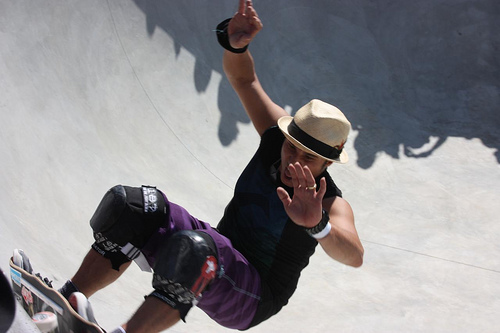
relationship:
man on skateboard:
[10, 2, 363, 331] [8, 256, 108, 332]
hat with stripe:
[278, 98, 350, 164] [289, 118, 343, 158]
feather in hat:
[333, 141, 347, 163] [278, 98, 350, 164]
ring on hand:
[306, 184, 317, 190] [276, 162, 327, 229]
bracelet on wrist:
[313, 222, 333, 239] [312, 213, 337, 246]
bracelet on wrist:
[301, 211, 329, 233] [312, 213, 337, 246]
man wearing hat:
[10, 2, 363, 331] [278, 98, 350, 164]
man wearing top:
[10, 2, 363, 331] [216, 126, 341, 305]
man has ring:
[10, 2, 363, 331] [306, 184, 317, 190]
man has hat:
[10, 2, 363, 331] [278, 98, 350, 164]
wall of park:
[0, 1, 498, 332] [0, 2, 498, 333]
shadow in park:
[134, 0, 499, 168] [0, 2, 498, 333]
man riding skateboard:
[10, 2, 363, 331] [8, 256, 108, 332]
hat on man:
[278, 98, 350, 164] [10, 2, 363, 331]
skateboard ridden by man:
[8, 256, 108, 332] [10, 2, 363, 331]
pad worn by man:
[153, 230, 206, 296] [10, 2, 363, 331]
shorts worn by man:
[137, 201, 263, 329] [10, 2, 363, 331]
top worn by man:
[216, 126, 341, 305] [10, 2, 363, 331]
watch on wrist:
[217, 17, 247, 53] [220, 33, 253, 58]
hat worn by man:
[278, 98, 350, 164] [10, 2, 363, 331]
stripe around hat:
[289, 118, 343, 158] [278, 98, 350, 164]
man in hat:
[10, 2, 363, 331] [278, 98, 350, 164]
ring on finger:
[306, 184, 317, 190] [303, 164, 316, 192]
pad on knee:
[153, 230, 206, 296] [157, 230, 216, 300]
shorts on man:
[137, 201, 263, 329] [10, 2, 363, 331]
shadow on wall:
[134, 0, 499, 168] [0, 1, 498, 332]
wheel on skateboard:
[33, 311, 58, 332] [8, 256, 108, 332]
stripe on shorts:
[218, 265, 262, 301] [137, 201, 263, 329]